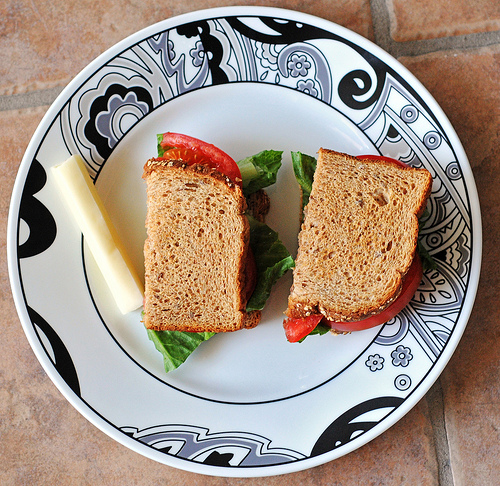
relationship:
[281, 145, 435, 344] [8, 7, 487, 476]
half of sandwich on a plate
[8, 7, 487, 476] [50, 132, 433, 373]
plate with food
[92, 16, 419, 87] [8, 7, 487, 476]
design on plate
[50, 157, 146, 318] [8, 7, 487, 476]
cheese on plate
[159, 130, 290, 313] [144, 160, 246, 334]
lettuce and tomatoes on bread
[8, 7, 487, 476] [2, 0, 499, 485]
plate on a tiled surface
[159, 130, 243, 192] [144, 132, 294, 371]
lettuce and tomatoes inside half of sandwich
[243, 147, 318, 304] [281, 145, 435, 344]
lettuce inside half of sandwich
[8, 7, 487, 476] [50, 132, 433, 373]
plate of food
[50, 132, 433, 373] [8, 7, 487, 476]
food on plate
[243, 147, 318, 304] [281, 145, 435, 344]
lettuce on half of sandwich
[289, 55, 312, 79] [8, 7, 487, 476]
flower design on plate